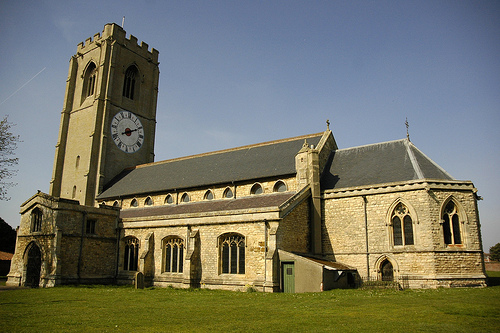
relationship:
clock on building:
[113, 111, 148, 163] [11, 17, 490, 290]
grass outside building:
[0, 286, 481, 332] [11, 17, 490, 290]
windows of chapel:
[75, 56, 150, 102] [48, 20, 160, 207]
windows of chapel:
[75, 56, 150, 102] [11, 17, 490, 290]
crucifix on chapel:
[324, 115, 338, 132] [11, 17, 490, 290]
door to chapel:
[275, 260, 303, 297] [11, 17, 490, 290]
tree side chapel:
[0, 107, 22, 206] [11, 17, 490, 290]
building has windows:
[11, 17, 490, 290] [75, 56, 150, 102]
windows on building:
[117, 59, 149, 101] [11, 17, 490, 290]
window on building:
[81, 60, 100, 103] [11, 17, 490, 290]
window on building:
[117, 234, 148, 274] [11, 17, 490, 290]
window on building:
[162, 234, 185, 274] [11, 17, 490, 290]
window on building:
[222, 235, 247, 273] [11, 17, 490, 290]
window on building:
[389, 205, 414, 248] [11, 17, 490, 290]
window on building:
[441, 194, 466, 244] [11, 17, 490, 290]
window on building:
[273, 181, 291, 194] [11, 17, 490, 290]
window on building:
[248, 181, 265, 197] [11, 17, 490, 290]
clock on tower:
[113, 111, 148, 163] [48, 20, 160, 207]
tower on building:
[48, 20, 160, 207] [11, 17, 490, 290]